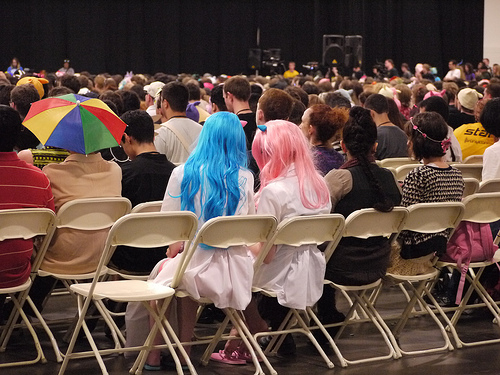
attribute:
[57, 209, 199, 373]
chair — light, empty, folding chari, white, ivory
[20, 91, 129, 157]
umbrella — multicolored, colored, on head, blue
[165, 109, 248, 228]
wig — blue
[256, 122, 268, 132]
horn — blue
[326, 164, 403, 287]
vest — black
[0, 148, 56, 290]
shirt — striped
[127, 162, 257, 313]
dress — white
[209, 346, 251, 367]
sandal — pink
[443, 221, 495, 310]
backpack — pink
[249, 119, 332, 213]
hair — pink, long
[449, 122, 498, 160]
t-shirt — yellow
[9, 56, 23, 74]
lady — elderly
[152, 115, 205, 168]
shirt 2 — white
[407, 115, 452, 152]
band — around head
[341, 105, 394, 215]
braided hair — long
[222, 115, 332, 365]
girl — sitting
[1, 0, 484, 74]
curtain — black